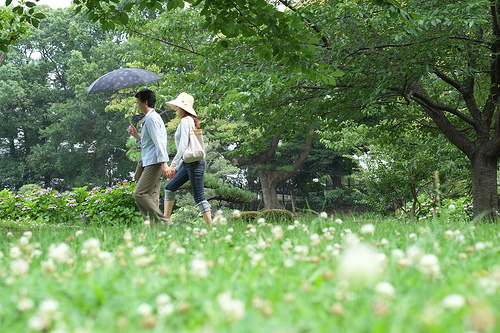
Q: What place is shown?
A: It is a field.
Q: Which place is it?
A: It is a field.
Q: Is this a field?
A: Yes, it is a field.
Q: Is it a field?
A: Yes, it is a field.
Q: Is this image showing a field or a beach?
A: It is showing a field.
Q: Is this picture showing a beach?
A: No, the picture is showing a field.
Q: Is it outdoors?
A: Yes, it is outdoors.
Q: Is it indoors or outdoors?
A: It is outdoors.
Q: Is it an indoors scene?
A: No, it is outdoors.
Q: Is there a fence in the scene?
A: No, there are no fences.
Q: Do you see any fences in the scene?
A: No, there are no fences.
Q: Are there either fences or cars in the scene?
A: No, there are no fences or cars.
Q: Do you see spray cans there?
A: No, there are no spray cans.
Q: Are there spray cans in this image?
A: No, there are no spray cans.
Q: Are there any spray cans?
A: No, there are no spray cans.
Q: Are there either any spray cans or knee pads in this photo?
A: No, there are no spray cans or knee pads.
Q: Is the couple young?
A: Yes, the couple is young.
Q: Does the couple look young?
A: Yes, the couple is young.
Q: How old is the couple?
A: The couple is young.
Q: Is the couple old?
A: No, the couple is young.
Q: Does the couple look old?
A: No, the couple is young.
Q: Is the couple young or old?
A: The couple is young.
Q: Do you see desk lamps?
A: No, there are no desk lamps.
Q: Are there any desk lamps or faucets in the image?
A: No, there are no desk lamps or faucets.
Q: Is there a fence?
A: No, there are no fences.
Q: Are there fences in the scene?
A: No, there are no fences.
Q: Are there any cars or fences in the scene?
A: No, there are no fences or cars.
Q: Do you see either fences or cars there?
A: No, there are no fences or cars.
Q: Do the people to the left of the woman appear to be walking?
A: Yes, the people are walking.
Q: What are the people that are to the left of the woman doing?
A: The people are walking.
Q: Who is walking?
A: The people are walking.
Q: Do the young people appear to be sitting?
A: No, the people are walking.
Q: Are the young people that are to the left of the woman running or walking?
A: The people are walking.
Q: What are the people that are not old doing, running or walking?
A: The people are walking.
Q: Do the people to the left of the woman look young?
A: Yes, the people are young.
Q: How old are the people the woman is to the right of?
A: The people are young.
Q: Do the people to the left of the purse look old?
A: No, the people are young.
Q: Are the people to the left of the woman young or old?
A: The people are young.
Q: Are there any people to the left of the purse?
A: Yes, there are people to the left of the purse.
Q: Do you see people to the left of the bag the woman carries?
A: Yes, there are people to the left of the purse.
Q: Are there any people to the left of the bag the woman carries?
A: Yes, there are people to the left of the purse.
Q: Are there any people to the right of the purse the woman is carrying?
A: No, the people are to the left of the purse.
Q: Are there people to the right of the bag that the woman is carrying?
A: No, the people are to the left of the purse.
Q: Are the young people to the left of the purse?
A: Yes, the people are to the left of the purse.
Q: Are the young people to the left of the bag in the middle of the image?
A: Yes, the people are to the left of the purse.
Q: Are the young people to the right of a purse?
A: No, the people are to the left of a purse.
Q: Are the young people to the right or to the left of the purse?
A: The people are to the left of the purse.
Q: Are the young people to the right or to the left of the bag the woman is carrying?
A: The people are to the left of the purse.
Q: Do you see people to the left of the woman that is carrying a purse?
A: Yes, there are people to the left of the woman.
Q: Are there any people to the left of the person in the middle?
A: Yes, there are people to the left of the woman.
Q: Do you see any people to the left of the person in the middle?
A: Yes, there are people to the left of the woman.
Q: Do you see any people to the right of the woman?
A: No, the people are to the left of the woman.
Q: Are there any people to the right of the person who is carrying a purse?
A: No, the people are to the left of the woman.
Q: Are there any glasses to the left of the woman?
A: No, there are people to the left of the woman.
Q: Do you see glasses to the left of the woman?
A: No, there are people to the left of the woman.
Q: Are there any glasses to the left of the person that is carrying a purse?
A: No, there are people to the left of the woman.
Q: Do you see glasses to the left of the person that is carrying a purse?
A: No, there are people to the left of the woman.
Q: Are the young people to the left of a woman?
A: Yes, the people are to the left of a woman.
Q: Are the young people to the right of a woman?
A: No, the people are to the left of a woman.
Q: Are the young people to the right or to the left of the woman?
A: The people are to the left of the woman.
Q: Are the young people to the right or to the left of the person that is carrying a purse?
A: The people are to the left of the woman.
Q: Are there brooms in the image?
A: No, there are no brooms.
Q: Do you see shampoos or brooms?
A: No, there are no brooms or shampoos.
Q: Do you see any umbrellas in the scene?
A: Yes, there is an umbrella.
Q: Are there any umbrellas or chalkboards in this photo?
A: Yes, there is an umbrella.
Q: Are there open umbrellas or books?
A: Yes, there is an open umbrella.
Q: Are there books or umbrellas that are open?
A: Yes, the umbrella is open.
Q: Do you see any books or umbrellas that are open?
A: Yes, the umbrella is open.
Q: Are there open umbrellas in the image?
A: Yes, there is an open umbrella.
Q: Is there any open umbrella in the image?
A: Yes, there is an open umbrella.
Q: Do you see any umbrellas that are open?
A: Yes, there is an open umbrella.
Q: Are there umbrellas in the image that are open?
A: Yes, there is an umbrella that is open.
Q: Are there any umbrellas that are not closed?
A: Yes, there is a open umbrella.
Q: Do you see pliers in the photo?
A: No, there are no pliers.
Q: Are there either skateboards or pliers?
A: No, there are no pliers or skateboards.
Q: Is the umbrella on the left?
A: Yes, the umbrella is on the left of the image.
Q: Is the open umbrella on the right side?
A: No, the umbrella is on the left of the image.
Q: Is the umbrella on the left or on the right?
A: The umbrella is on the left of the image.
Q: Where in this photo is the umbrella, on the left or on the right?
A: The umbrella is on the left of the image.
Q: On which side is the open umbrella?
A: The umbrella is on the left of the image.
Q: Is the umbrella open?
A: Yes, the umbrella is open.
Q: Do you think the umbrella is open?
A: Yes, the umbrella is open.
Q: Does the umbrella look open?
A: Yes, the umbrella is open.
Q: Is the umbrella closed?
A: No, the umbrella is open.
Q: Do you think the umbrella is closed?
A: No, the umbrella is open.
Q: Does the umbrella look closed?
A: No, the umbrella is open.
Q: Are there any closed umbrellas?
A: No, there is an umbrella but it is open.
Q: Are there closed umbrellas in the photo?
A: No, there is an umbrella but it is open.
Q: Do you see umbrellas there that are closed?
A: No, there is an umbrella but it is open.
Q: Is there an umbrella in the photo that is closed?
A: No, there is an umbrella but it is open.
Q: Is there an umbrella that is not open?
A: No, there is an umbrella but it is open.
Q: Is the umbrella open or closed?
A: The umbrella is open.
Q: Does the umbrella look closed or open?
A: The umbrella is open.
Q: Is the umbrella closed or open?
A: The umbrella is open.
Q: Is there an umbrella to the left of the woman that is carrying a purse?
A: Yes, there is an umbrella to the left of the woman.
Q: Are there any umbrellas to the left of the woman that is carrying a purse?
A: Yes, there is an umbrella to the left of the woman.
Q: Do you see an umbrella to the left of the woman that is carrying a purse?
A: Yes, there is an umbrella to the left of the woman.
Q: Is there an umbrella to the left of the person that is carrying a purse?
A: Yes, there is an umbrella to the left of the woman.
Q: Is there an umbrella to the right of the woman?
A: No, the umbrella is to the left of the woman.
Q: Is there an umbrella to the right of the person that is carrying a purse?
A: No, the umbrella is to the left of the woman.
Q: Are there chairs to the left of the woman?
A: No, there is an umbrella to the left of the woman.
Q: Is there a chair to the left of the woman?
A: No, there is an umbrella to the left of the woman.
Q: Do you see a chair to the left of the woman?
A: No, there is an umbrella to the left of the woman.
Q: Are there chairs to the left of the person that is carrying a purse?
A: No, there is an umbrella to the left of the woman.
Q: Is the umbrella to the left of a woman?
A: Yes, the umbrella is to the left of a woman.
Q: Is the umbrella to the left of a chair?
A: No, the umbrella is to the left of a woman.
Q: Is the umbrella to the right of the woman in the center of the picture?
A: No, the umbrella is to the left of the woman.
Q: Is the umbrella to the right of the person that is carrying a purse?
A: No, the umbrella is to the left of the woman.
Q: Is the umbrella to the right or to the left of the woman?
A: The umbrella is to the left of the woman.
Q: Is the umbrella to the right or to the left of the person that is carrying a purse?
A: The umbrella is to the left of the woman.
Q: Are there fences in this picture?
A: No, there are no fences.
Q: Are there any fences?
A: No, there are no fences.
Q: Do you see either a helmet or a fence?
A: No, there are no fences or helmets.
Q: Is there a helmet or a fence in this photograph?
A: No, there are no fences or helmets.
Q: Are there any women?
A: Yes, there is a woman.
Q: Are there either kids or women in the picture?
A: Yes, there is a woman.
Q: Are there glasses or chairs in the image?
A: No, there are no glasses or chairs.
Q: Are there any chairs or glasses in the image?
A: No, there are no glasses or chairs.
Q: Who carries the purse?
A: The woman carries the purse.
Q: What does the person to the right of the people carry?
A: The woman carries a purse.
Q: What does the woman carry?
A: The woman carries a purse.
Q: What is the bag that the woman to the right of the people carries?
A: The bag is a purse.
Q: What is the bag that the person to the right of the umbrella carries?
A: The bag is a purse.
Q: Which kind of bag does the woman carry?
A: The woman carries a purse.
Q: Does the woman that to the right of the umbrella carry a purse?
A: Yes, the woman carries a purse.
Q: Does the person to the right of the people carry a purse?
A: Yes, the woman carries a purse.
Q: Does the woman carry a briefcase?
A: No, the woman carries a purse.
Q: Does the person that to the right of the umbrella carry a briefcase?
A: No, the woman carries a purse.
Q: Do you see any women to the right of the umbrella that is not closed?
A: Yes, there is a woman to the right of the umbrella.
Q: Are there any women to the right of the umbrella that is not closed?
A: Yes, there is a woman to the right of the umbrella.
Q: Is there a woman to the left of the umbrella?
A: No, the woman is to the right of the umbrella.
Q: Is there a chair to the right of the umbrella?
A: No, there is a woman to the right of the umbrella.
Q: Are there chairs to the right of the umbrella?
A: No, there is a woman to the right of the umbrella.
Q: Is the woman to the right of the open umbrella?
A: Yes, the woman is to the right of the umbrella.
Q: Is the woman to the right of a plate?
A: No, the woman is to the right of the umbrella.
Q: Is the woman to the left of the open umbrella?
A: No, the woman is to the right of the umbrella.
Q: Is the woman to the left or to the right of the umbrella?
A: The woman is to the right of the umbrella.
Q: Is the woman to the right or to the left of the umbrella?
A: The woman is to the right of the umbrella.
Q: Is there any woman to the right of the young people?
A: Yes, there is a woman to the right of the people.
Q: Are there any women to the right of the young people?
A: Yes, there is a woman to the right of the people.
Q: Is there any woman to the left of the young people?
A: No, the woman is to the right of the people.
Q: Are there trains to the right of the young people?
A: No, there is a woman to the right of the people.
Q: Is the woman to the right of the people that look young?
A: Yes, the woman is to the right of the people.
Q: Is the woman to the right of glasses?
A: No, the woman is to the right of the people.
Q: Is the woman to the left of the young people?
A: No, the woman is to the right of the people.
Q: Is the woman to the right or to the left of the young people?
A: The woman is to the right of the people.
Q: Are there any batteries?
A: No, there are no batteries.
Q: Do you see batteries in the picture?
A: No, there are no batteries.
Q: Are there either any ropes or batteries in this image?
A: No, there are no batteries or ropes.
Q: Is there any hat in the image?
A: Yes, there is a hat.